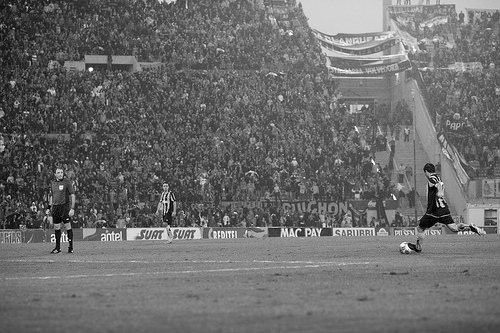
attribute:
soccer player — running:
[410, 143, 481, 251]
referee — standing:
[47, 165, 80, 255]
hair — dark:
[421, 163, 439, 174]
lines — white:
[0, 254, 375, 283]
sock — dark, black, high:
[66, 230, 74, 255]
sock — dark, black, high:
[53, 227, 64, 254]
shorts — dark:
[50, 203, 72, 227]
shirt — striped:
[158, 189, 180, 218]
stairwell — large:
[358, 126, 421, 229]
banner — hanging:
[315, 27, 398, 46]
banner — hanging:
[323, 53, 415, 79]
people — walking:
[389, 136, 398, 158]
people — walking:
[404, 124, 415, 144]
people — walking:
[396, 160, 409, 185]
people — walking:
[405, 186, 419, 212]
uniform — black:
[418, 175, 451, 228]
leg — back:
[450, 220, 484, 235]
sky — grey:
[305, 1, 387, 34]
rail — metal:
[388, 132, 422, 210]